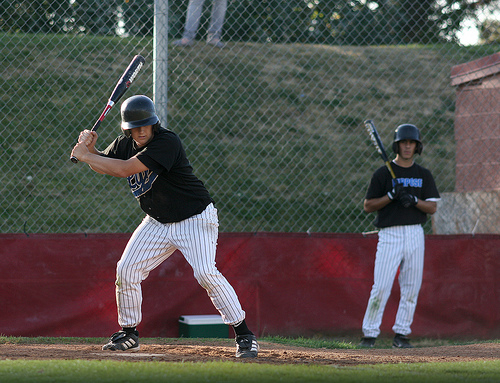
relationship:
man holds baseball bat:
[68, 95, 266, 361] [66, 48, 154, 165]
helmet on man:
[113, 91, 163, 125] [68, 95, 266, 361]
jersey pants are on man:
[116, 201, 245, 332] [68, 95, 266, 361]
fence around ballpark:
[1, 3, 498, 234] [4, 0, 497, 382]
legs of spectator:
[358, 219, 420, 336] [358, 121, 439, 348]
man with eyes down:
[68, 95, 266, 361] [125, 117, 156, 137]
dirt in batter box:
[192, 344, 210, 357] [3, 341, 354, 363]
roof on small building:
[451, 53, 499, 85] [445, 51, 499, 197]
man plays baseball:
[68, 95, 266, 361] [4, 38, 489, 371]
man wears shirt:
[68, 95, 266, 361] [99, 131, 217, 223]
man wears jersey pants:
[68, 95, 266, 361] [116, 201, 245, 332]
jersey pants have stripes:
[116, 201, 245, 332] [118, 230, 156, 320]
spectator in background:
[358, 121, 439, 348] [303, 21, 498, 338]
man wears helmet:
[68, 95, 266, 361] [113, 91, 163, 125]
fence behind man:
[1, 3, 498, 234] [68, 95, 266, 361]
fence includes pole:
[1, 3, 498, 234] [152, 0, 168, 129]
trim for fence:
[2, 227, 500, 334] [1, 3, 498, 234]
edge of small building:
[455, 68, 464, 195] [445, 51, 499, 197]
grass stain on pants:
[368, 287, 390, 319] [352, 222, 427, 332]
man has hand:
[68, 95, 266, 361] [70, 143, 91, 159]